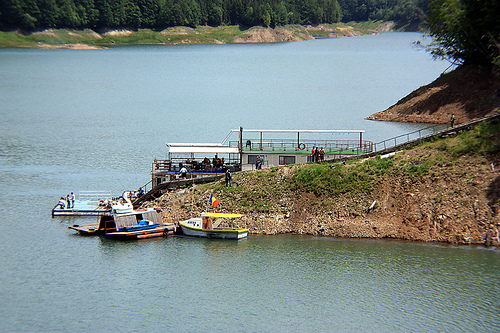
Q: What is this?
A: A boat launch.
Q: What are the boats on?
A: A lake.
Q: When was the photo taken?
A: During the day.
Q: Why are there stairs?
A: To walk down to the water.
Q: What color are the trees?
A: Green.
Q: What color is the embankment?
A: Brown.